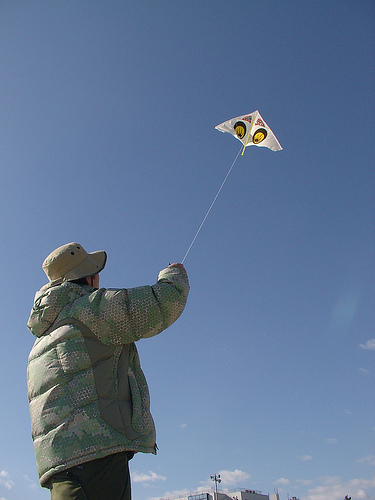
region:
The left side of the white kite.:
[252, 111, 281, 168]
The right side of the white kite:
[209, 100, 248, 164]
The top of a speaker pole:
[203, 471, 232, 487]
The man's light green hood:
[22, 283, 64, 335]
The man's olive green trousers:
[51, 466, 127, 498]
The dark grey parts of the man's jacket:
[87, 339, 135, 433]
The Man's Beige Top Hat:
[42, 230, 108, 281]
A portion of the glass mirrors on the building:
[186, 489, 211, 499]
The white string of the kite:
[169, 153, 239, 267]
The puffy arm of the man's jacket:
[88, 275, 185, 350]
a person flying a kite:
[12, 221, 236, 497]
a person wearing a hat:
[19, 199, 226, 490]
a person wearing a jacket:
[1, 195, 268, 496]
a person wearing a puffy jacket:
[14, 215, 235, 489]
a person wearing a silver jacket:
[17, 223, 223, 482]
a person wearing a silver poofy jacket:
[27, 224, 198, 453]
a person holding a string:
[11, 203, 345, 396]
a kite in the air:
[172, 20, 312, 198]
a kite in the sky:
[198, 73, 345, 209]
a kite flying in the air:
[192, 72, 310, 168]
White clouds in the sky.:
[280, 454, 372, 490]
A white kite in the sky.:
[212, 108, 283, 158]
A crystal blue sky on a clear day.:
[231, 226, 361, 296]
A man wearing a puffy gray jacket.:
[29, 230, 190, 481]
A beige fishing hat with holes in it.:
[40, 242, 107, 287]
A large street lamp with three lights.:
[208, 465, 223, 498]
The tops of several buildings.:
[187, 486, 301, 498]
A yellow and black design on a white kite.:
[252, 127, 267, 147]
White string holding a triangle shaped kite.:
[179, 146, 251, 263]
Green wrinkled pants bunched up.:
[50, 457, 133, 498]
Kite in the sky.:
[167, 74, 305, 182]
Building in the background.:
[179, 461, 243, 497]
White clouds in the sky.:
[204, 446, 280, 496]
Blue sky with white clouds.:
[208, 388, 304, 491]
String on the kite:
[125, 149, 273, 244]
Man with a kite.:
[21, 224, 216, 493]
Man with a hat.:
[32, 215, 131, 306]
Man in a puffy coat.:
[9, 228, 276, 498]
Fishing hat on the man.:
[20, 219, 123, 316]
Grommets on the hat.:
[40, 226, 114, 305]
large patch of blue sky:
[240, 225, 362, 300]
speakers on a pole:
[205, 466, 220, 489]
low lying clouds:
[303, 468, 363, 488]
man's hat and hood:
[20, 236, 99, 320]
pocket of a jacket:
[120, 366, 140, 421]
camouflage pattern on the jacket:
[36, 405, 99, 438]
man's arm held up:
[115, 261, 185, 352]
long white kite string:
[180, 150, 240, 255]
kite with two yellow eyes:
[205, 98, 282, 158]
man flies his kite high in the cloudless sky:
[36, 84, 287, 392]